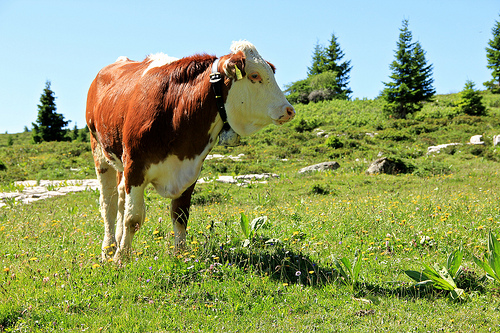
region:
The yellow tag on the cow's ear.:
[231, 60, 242, 75]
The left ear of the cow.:
[218, 51, 248, 82]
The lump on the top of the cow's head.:
[228, 42, 258, 59]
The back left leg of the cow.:
[86, 146, 119, 262]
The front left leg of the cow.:
[115, 160, 135, 256]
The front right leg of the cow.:
[166, 186, 204, 261]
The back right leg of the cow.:
[111, 173, 127, 254]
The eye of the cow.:
[246, 65, 262, 85]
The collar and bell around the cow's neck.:
[210, 61, 245, 141]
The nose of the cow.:
[279, 102, 299, 124]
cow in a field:
[64, 29, 304, 305]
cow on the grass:
[78, 35, 308, 256]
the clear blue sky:
[46, 10, 119, 37]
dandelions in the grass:
[285, 263, 320, 283]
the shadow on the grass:
[257, 233, 391, 309]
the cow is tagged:
[228, 65, 246, 87]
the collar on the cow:
[193, 52, 247, 138]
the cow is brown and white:
[70, 44, 345, 294]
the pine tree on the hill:
[363, 20, 448, 96]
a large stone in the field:
[358, 143, 410, 180]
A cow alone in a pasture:
[57, 52, 323, 265]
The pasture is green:
[1, 146, 483, 323]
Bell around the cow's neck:
[200, 50, 245, 151]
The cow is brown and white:
[38, 27, 295, 277]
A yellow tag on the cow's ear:
[224, 54, 259, 87]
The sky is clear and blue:
[17, 0, 488, 132]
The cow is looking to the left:
[203, 34, 329, 173]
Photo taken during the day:
[12, 13, 488, 323]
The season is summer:
[15, 12, 485, 321]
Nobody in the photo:
[17, 0, 488, 323]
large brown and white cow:
[93, 39, 300, 277]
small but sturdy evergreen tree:
[32, 81, 81, 146]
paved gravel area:
[19, 166, 102, 226]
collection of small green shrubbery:
[289, 62, 363, 108]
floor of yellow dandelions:
[8, 229, 110, 313]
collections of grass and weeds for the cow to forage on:
[206, 213, 421, 315]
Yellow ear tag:
[221, 53, 248, 97]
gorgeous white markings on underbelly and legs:
[78, 161, 223, 273]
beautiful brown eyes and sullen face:
[241, 67, 299, 129]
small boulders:
[357, 144, 433, 189]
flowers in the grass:
[167, 232, 342, 322]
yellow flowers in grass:
[143, 219, 231, 259]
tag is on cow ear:
[211, 29, 267, 152]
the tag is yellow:
[225, 62, 257, 88]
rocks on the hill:
[305, 102, 490, 186]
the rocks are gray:
[299, 144, 420, 195]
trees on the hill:
[313, 40, 373, 108]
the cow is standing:
[85, 53, 281, 245]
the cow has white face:
[227, 52, 304, 161]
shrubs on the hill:
[367, 82, 482, 125]